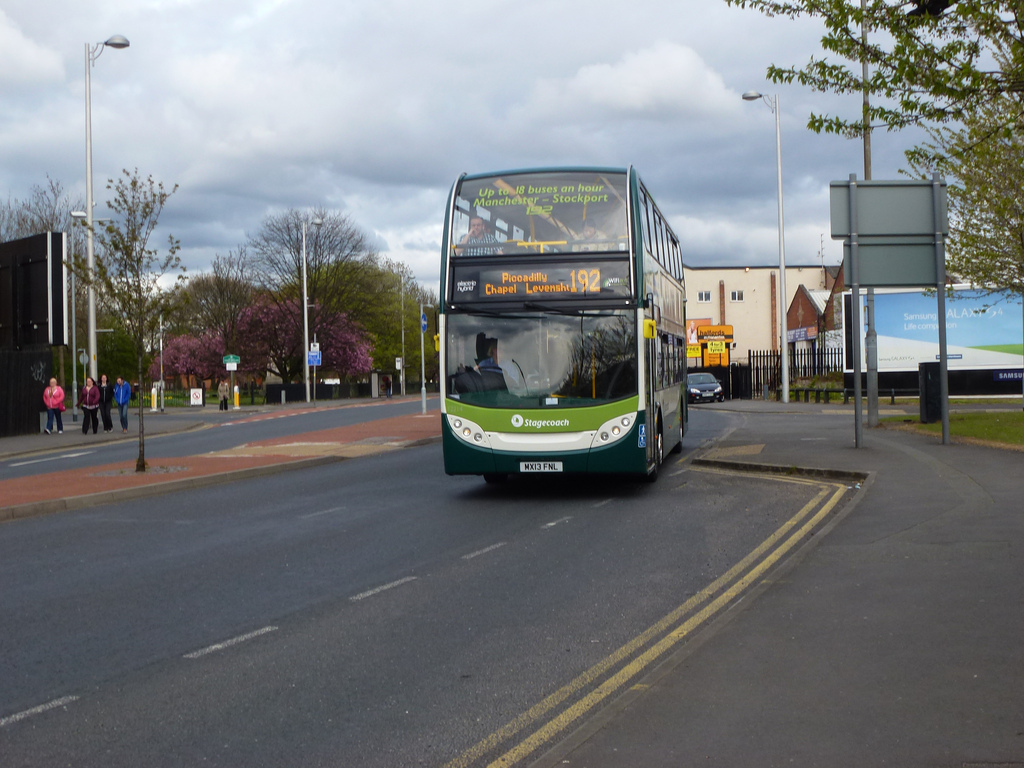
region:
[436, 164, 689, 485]
green double decker bus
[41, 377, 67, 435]
person in a pink jacket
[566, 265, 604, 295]
the number 192 on the bus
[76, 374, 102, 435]
person in a maroon jacket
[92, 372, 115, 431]
person in a black jacket and black pants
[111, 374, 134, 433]
person in a blue jacket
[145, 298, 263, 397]
pink blooming tree in the park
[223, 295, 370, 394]
pink blooming tree in the park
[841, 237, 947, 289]
smaller gray road sign facing away from the camera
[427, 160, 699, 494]
A DOUBLE DECKER BUS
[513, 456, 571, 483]
A LICENSE PLATE ON A BUS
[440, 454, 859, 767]
A DOUBLE YELLOW LINE ON THE STREET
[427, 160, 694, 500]
THE NUMBER 192 BUS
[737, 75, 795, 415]
AN OUTDOOR STREET LIGHT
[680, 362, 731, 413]
A CAR IN THE BACKGROUND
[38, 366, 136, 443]
FOUR PEOPLE WALKING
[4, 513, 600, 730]
BROKEN WHITE LINES ON THE PAVEMENT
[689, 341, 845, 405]
A BLACK IRON FENCE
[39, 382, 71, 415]
A PINK JACKET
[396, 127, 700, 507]
green and black double deck bus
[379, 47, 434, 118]
white clouds in blue sky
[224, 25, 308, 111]
white clouds in blue sky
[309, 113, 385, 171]
white clouds in blue sky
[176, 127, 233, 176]
white clouds in blue sky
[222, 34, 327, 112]
white clouds in blue sky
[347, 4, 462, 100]
white clouds in blue sky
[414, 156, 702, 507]
the bus is double decker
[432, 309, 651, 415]
the windshield of the bus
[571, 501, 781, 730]
a double yellow line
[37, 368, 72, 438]
person has a red top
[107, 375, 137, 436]
person wears blue top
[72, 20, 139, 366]
the light of a pole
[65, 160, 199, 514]
a tree on the center of street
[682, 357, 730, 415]
a car is black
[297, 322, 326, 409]
the sign is blue and white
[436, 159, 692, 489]
green and white doubledecker bus being driven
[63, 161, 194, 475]
small green tree planted in street divider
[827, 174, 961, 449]
back side of two rectilinear street signs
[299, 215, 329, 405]
metalic streetlight turned off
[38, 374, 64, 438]
pedestrian with hands in pockets of pink jacket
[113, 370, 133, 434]
pedestrian in medium blue jacket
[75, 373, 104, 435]
pedestrian maroon jacket and dark pants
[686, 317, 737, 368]
yellow, orange, and black street signage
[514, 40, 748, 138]
a large white cloud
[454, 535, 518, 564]
a white street marking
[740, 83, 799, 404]
a tall gray street light pole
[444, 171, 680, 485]
a large double decker bus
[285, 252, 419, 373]
a large green tree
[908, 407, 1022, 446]
a section of green grass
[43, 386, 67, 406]
a woman's pink jacket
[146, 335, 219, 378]
a large purple tree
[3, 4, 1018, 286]
cloud cover in daytime sky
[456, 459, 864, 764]
double yellow lines on asphalt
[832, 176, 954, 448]
back of signs on poles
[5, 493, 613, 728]
faded white broken lines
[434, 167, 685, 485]
front of double decker bus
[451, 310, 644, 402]
reflection on glass windshield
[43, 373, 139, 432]
group of walking people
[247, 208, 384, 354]
tree branches with no leaves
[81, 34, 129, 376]
street light on pole